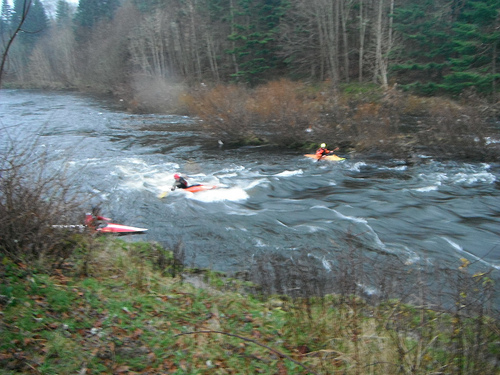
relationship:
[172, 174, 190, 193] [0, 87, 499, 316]
person in river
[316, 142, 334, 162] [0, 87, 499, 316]
person in river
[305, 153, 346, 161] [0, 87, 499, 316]
kayak in river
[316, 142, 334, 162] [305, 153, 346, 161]
person in kayak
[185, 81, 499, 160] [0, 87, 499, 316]
grass by river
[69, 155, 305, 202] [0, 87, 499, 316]
wave in river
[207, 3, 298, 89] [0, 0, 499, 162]
tree in woods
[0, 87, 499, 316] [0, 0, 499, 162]
river in woods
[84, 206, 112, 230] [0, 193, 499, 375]
person near land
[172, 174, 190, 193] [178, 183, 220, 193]
person in kayak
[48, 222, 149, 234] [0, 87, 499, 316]
kayak in river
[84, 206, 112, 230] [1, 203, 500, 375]
person by shore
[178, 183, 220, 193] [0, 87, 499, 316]
kayak in river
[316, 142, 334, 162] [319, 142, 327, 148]
person wearing helmet